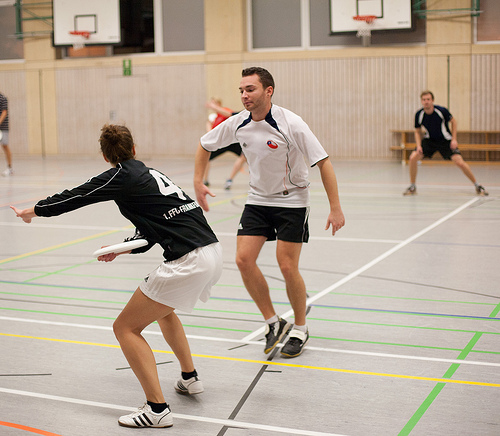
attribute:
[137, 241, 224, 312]
shorts — white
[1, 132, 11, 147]
shorts — white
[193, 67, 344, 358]
man — moving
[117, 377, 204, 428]
sneakers — white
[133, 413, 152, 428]
stripes — black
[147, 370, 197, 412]
socks — black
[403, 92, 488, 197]
man — lunging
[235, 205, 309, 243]
shorts — black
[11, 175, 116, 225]
arm — stretched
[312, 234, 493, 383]
lines — colored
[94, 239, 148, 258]
frisbee — white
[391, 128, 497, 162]
benches — wooden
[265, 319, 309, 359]
shoes — black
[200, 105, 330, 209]
shirt — white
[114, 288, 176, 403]
leg — shaved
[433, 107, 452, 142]
stripe — white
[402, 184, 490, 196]
shoes — black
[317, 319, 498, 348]
lines — green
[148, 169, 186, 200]
number — white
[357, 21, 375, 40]
net — white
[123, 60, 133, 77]
sign — green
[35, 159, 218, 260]
jacket — black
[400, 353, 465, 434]
stripe — green